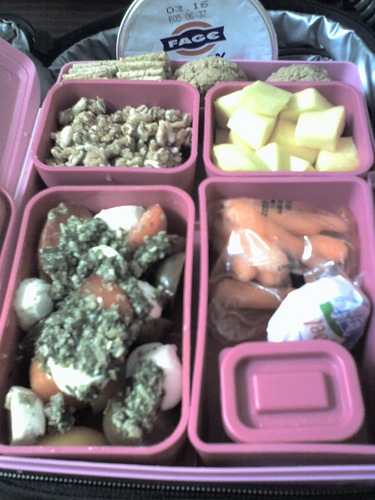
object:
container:
[201, 82, 374, 178]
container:
[1, 184, 196, 457]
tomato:
[30, 360, 58, 398]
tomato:
[79, 276, 134, 319]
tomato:
[125, 203, 167, 249]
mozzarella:
[94, 205, 152, 240]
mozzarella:
[12, 277, 54, 329]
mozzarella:
[127, 342, 182, 410]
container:
[217, 340, 364, 444]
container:
[186, 175, 374, 469]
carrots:
[218, 279, 295, 307]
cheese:
[266, 275, 372, 352]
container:
[31, 80, 200, 185]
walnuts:
[154, 118, 169, 148]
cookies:
[267, 63, 334, 82]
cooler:
[0, 3, 373, 500]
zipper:
[1, 470, 374, 499]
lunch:
[1, 0, 370, 446]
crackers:
[116, 68, 166, 78]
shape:
[251, 371, 334, 416]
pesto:
[34, 297, 123, 374]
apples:
[292, 104, 345, 152]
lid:
[0, 38, 40, 197]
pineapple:
[227, 107, 279, 150]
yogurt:
[116, 1, 278, 61]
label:
[160, 21, 227, 58]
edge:
[1, 12, 372, 106]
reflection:
[226, 227, 272, 263]